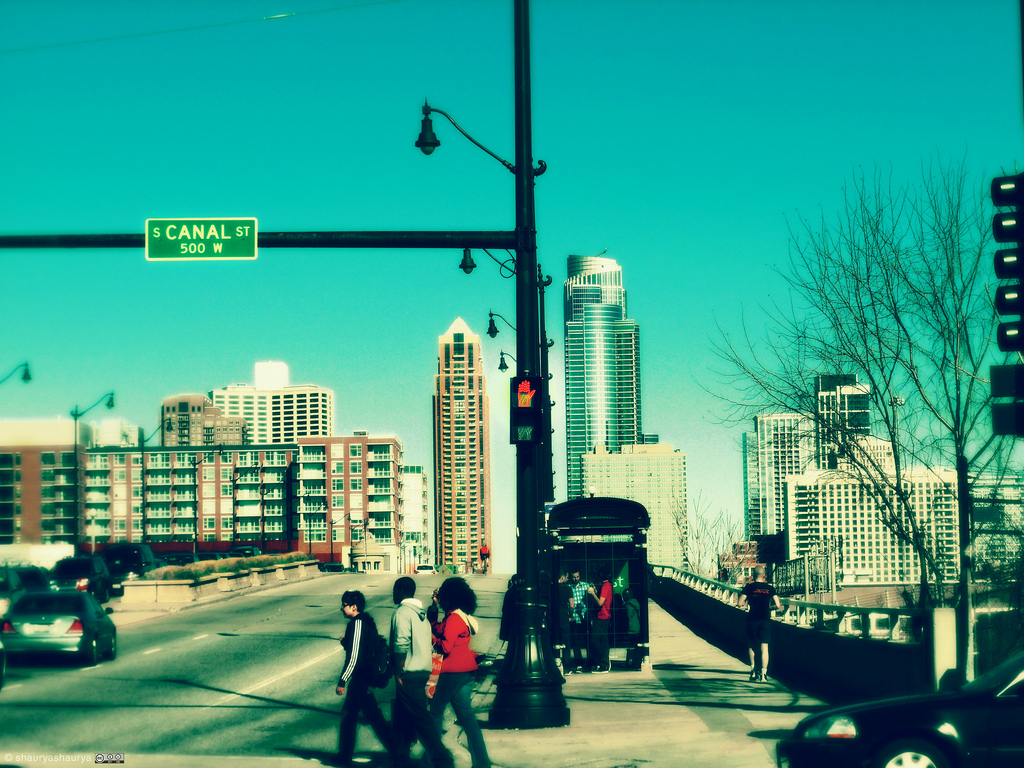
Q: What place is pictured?
A: It is a road.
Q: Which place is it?
A: It is a road.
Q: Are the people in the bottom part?
A: Yes, the people are in the bottom of the image.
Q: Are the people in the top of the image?
A: No, the people are in the bottom of the image.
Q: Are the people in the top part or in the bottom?
A: The people are in the bottom of the image.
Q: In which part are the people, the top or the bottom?
A: The people are in the bottom of the image.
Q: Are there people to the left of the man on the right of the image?
A: Yes, there are people to the left of the man.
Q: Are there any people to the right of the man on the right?
A: No, the people are to the left of the man.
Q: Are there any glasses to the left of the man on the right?
A: No, there are people to the left of the man.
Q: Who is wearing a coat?
A: The people are wearing a coat.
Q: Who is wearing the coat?
A: The people are wearing a coat.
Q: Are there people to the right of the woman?
A: Yes, there are people to the right of the woman.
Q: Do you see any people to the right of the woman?
A: Yes, there are people to the right of the woman.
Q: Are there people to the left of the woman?
A: No, the people are to the right of the woman.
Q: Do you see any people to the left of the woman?
A: No, the people are to the right of the woman.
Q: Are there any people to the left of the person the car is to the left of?
A: No, the people are to the right of the woman.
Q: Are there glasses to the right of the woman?
A: No, there are people to the right of the woman.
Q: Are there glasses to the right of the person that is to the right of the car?
A: No, there are people to the right of the woman.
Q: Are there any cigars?
A: No, there are no cigars.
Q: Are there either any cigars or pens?
A: No, there are no cigars or pens.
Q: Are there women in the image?
A: Yes, there is a woman.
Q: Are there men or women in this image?
A: Yes, there is a woman.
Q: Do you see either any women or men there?
A: Yes, there is a woman.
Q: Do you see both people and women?
A: Yes, there are both a woman and a person.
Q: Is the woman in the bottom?
A: Yes, the woman is in the bottom of the image.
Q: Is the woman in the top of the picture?
A: No, the woman is in the bottom of the image.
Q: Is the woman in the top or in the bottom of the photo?
A: The woman is in the bottom of the image.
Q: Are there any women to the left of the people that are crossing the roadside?
A: Yes, there is a woman to the left of the people.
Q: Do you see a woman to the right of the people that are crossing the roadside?
A: No, the woman is to the left of the people.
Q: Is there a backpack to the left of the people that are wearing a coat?
A: No, there is a woman to the left of the people.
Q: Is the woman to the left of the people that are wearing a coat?
A: Yes, the woman is to the left of the people.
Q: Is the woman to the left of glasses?
A: No, the woman is to the left of the people.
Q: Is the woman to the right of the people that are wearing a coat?
A: No, the woman is to the left of the people.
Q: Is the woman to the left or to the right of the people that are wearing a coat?
A: The woman is to the left of the people.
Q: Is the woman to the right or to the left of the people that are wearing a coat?
A: The woman is to the left of the people.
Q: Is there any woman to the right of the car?
A: Yes, there is a woman to the right of the car.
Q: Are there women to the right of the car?
A: Yes, there is a woman to the right of the car.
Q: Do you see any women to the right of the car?
A: Yes, there is a woman to the right of the car.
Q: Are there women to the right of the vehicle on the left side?
A: Yes, there is a woman to the right of the car.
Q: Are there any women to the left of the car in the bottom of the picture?
A: No, the woman is to the right of the car.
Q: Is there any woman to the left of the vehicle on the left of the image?
A: No, the woman is to the right of the car.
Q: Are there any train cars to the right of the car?
A: No, there is a woman to the right of the car.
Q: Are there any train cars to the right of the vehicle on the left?
A: No, there is a woman to the right of the car.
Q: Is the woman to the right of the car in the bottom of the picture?
A: Yes, the woman is to the right of the car.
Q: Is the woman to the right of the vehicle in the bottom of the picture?
A: Yes, the woman is to the right of the car.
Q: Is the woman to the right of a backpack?
A: No, the woman is to the right of the car.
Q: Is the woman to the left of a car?
A: No, the woman is to the right of a car.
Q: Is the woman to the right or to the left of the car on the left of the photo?
A: The woman is to the right of the car.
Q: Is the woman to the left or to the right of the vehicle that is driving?
A: The woman is to the right of the car.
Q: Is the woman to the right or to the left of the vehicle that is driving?
A: The woman is to the right of the car.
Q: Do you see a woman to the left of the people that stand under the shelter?
A: Yes, there is a woman to the left of the people.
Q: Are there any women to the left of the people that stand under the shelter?
A: Yes, there is a woman to the left of the people.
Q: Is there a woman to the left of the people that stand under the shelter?
A: Yes, there is a woman to the left of the people.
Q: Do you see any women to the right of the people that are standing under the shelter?
A: No, the woman is to the left of the people.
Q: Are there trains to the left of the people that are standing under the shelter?
A: No, there is a woman to the left of the people.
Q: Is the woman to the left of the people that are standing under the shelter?
A: Yes, the woman is to the left of the people.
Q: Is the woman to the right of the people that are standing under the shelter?
A: No, the woman is to the left of the people.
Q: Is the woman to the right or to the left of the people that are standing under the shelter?
A: The woman is to the left of the people.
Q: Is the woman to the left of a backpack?
A: No, the woman is to the left of a person.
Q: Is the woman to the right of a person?
A: No, the woman is to the left of a person.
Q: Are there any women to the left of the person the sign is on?
A: Yes, there is a woman to the left of the person.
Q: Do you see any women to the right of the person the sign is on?
A: No, the woman is to the left of the person.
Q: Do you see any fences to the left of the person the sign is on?
A: No, there is a woman to the left of the person.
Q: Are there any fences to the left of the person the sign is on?
A: No, there is a woman to the left of the person.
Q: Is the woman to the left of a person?
A: Yes, the woman is to the left of a person.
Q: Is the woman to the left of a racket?
A: No, the woman is to the left of a person.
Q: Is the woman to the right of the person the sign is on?
A: No, the woman is to the left of the person.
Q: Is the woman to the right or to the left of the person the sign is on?
A: The woman is to the left of the person.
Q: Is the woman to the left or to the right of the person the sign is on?
A: The woman is to the left of the person.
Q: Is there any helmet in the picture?
A: No, there are no helmets.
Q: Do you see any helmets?
A: No, there are no helmets.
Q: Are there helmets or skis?
A: No, there are no helmets or skis.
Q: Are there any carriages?
A: No, there are no carriages.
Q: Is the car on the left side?
A: Yes, the car is on the left of the image.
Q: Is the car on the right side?
A: No, the car is on the left of the image.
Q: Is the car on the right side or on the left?
A: The car is on the left of the image.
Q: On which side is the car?
A: The car is on the left of the image.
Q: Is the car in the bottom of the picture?
A: Yes, the car is in the bottom of the image.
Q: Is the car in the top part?
A: No, the car is in the bottom of the image.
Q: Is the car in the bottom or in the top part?
A: The car is in the bottom of the image.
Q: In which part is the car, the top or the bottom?
A: The car is in the bottom of the image.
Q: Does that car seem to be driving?
A: Yes, the car is driving.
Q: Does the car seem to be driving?
A: Yes, the car is driving.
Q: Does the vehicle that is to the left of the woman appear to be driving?
A: Yes, the car is driving.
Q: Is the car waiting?
A: No, the car is driving.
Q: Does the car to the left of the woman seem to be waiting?
A: No, the car is driving.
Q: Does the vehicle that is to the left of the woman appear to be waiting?
A: No, the car is driving.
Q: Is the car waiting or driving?
A: The car is driving.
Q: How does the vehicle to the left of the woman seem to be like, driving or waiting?
A: The car is driving.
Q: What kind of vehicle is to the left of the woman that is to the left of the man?
A: The vehicle is a car.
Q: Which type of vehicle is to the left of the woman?
A: The vehicle is a car.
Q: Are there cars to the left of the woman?
A: Yes, there is a car to the left of the woman.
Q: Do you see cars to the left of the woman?
A: Yes, there is a car to the left of the woman.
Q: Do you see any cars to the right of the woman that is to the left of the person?
A: No, the car is to the left of the woman.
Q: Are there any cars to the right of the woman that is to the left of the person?
A: No, the car is to the left of the woman.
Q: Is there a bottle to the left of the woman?
A: No, there is a car to the left of the woman.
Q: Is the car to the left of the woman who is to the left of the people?
A: Yes, the car is to the left of the woman.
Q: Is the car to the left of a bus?
A: No, the car is to the left of the woman.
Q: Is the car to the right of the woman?
A: No, the car is to the left of the woman.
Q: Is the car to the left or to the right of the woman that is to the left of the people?
A: The car is to the left of the woman.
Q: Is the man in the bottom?
A: Yes, the man is in the bottom of the image.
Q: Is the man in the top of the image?
A: No, the man is in the bottom of the image.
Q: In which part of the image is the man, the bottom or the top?
A: The man is in the bottom of the image.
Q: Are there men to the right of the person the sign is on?
A: Yes, there is a man to the right of the person.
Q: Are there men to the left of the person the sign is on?
A: No, the man is to the right of the person.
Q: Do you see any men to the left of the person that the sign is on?
A: No, the man is to the right of the person.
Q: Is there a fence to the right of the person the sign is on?
A: No, there is a man to the right of the person.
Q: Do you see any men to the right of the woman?
A: Yes, there is a man to the right of the woman.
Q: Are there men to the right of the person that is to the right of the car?
A: Yes, there is a man to the right of the woman.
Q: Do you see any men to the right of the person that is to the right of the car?
A: Yes, there is a man to the right of the woman.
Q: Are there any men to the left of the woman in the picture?
A: No, the man is to the right of the woman.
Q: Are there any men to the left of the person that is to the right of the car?
A: No, the man is to the right of the woman.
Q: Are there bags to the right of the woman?
A: No, there is a man to the right of the woman.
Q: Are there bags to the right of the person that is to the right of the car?
A: No, there is a man to the right of the woman.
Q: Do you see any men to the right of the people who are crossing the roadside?
A: Yes, there is a man to the right of the people.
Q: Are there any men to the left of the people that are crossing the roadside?
A: No, the man is to the right of the people.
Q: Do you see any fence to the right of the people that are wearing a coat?
A: No, there is a man to the right of the people.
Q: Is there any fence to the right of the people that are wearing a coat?
A: No, there is a man to the right of the people.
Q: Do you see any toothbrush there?
A: No, there are no toothbrushes.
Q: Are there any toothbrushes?
A: No, there are no toothbrushes.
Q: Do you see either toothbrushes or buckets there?
A: No, there are no toothbrushes or buckets.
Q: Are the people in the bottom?
A: Yes, the people are in the bottom of the image.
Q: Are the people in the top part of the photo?
A: No, the people are in the bottom of the image.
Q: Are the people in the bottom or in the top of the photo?
A: The people are in the bottom of the image.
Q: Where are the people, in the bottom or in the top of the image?
A: The people are in the bottom of the image.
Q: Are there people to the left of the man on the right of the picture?
A: Yes, there are people to the left of the man.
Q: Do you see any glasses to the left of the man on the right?
A: No, there are people to the left of the man.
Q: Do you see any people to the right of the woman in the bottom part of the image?
A: Yes, there are people to the right of the woman.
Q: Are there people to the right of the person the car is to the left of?
A: Yes, there are people to the right of the woman.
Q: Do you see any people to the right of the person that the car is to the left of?
A: Yes, there are people to the right of the woman.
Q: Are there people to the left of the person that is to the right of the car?
A: No, the people are to the right of the woman.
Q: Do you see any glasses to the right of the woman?
A: No, there are people to the right of the woman.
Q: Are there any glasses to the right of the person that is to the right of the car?
A: No, there are people to the right of the woman.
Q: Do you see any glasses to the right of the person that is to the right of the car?
A: No, there are people to the right of the woman.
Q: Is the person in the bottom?
A: Yes, the person is in the bottom of the image.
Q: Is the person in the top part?
A: No, the person is in the bottom of the image.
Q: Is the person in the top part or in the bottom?
A: The person is in the bottom of the image.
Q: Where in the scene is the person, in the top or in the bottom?
A: The person is in the bottom of the image.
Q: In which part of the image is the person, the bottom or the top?
A: The person is in the bottom of the image.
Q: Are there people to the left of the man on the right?
A: Yes, there is a person to the left of the man.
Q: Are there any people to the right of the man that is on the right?
A: No, the person is to the left of the man.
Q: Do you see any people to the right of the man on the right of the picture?
A: No, the person is to the left of the man.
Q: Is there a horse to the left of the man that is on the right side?
A: No, there is a person to the left of the man.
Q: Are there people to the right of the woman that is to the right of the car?
A: Yes, there is a person to the right of the woman.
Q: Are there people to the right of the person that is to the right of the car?
A: Yes, there is a person to the right of the woman.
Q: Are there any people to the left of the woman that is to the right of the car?
A: No, the person is to the right of the woman.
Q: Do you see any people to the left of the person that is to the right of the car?
A: No, the person is to the right of the woman.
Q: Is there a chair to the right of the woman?
A: No, there is a person to the right of the woman.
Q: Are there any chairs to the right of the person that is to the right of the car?
A: No, there is a person to the right of the woman.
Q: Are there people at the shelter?
A: Yes, there is a person at the shelter.